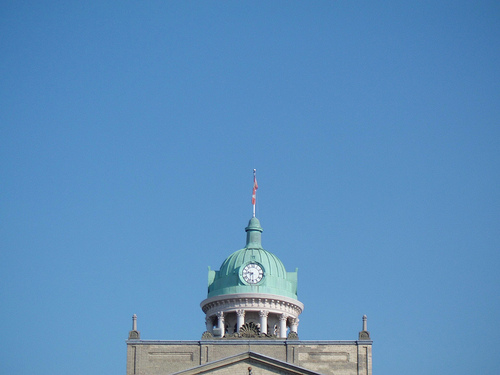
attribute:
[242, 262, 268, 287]
clock — white face, white, round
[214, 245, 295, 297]
dome — light blue, tower, green, white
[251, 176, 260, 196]
flag — peak, red, white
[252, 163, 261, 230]
pole — white, flag, tall, small, grey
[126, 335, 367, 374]
building — white, columnar, historical, grey, green, dome shaped, large, capital, copper, stained concrete, concrete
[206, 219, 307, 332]
clock tower — dome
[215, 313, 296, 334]
columns — white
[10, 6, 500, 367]
sky — blue, part, clear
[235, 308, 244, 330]
pillar — white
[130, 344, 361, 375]
wall — grey, stone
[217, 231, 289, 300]
roof — green, copper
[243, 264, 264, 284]
numbers — roman numerals, black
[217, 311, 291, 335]
pillars — white, top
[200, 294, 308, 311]
base — white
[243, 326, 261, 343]
design — emblem